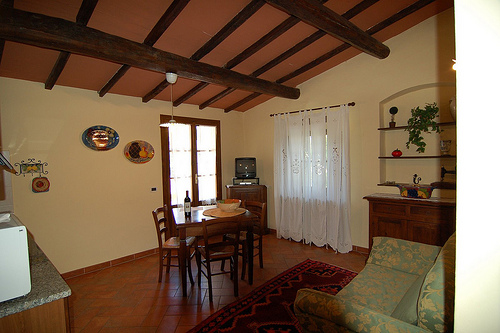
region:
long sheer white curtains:
[258, 98, 377, 275]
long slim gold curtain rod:
[265, 98, 370, 116]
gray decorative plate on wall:
[69, 118, 125, 154]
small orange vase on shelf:
[385, 143, 405, 158]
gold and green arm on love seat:
[299, 290, 387, 314]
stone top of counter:
[31, 259, 81, 296]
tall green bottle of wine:
[178, 188, 199, 222]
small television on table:
[230, 141, 269, 177]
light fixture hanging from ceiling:
[152, 73, 196, 130]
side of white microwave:
[10, 222, 46, 278]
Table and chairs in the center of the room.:
[130, 178, 279, 291]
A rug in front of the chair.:
[198, 246, 362, 318]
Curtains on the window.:
[268, 96, 367, 247]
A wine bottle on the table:
[170, 188, 207, 220]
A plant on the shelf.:
[391, 98, 449, 158]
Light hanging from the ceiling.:
[155, 58, 181, 133]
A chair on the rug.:
[288, 224, 448, 330]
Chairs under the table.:
[175, 203, 275, 288]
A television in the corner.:
[219, 147, 274, 193]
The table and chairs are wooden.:
[159, 188, 276, 286]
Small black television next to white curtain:
[232, 152, 259, 182]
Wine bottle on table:
[181, 189, 194, 216]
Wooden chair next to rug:
[195, 216, 242, 306]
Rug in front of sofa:
[188, 250, 358, 332]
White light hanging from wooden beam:
[155, 71, 187, 131]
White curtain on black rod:
[268, 104, 355, 256]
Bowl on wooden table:
[217, 197, 245, 213]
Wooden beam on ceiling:
[0, 3, 307, 100]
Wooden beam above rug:
[267, 0, 394, 59]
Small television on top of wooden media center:
[232, 154, 257, 179]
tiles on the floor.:
[115, 293, 150, 315]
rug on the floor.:
[298, 268, 328, 280]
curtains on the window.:
[310, 135, 335, 186]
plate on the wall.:
[85, 121, 116, 156]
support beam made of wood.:
[310, 13, 367, 47]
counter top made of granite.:
[37, 265, 48, 297]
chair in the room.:
[363, 261, 408, 301]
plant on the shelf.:
[406, 110, 433, 149]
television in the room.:
[236, 157, 255, 177]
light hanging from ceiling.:
[165, 99, 177, 131]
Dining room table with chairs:
[132, 184, 277, 261]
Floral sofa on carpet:
[302, 236, 379, 313]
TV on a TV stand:
[214, 140, 306, 212]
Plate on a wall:
[83, 116, 126, 165]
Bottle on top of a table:
[171, 183, 193, 222]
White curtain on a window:
[258, 112, 362, 251]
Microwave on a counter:
[1, 201, 53, 295]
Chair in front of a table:
[143, 197, 178, 289]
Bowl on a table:
[222, 195, 242, 219]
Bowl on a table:
[211, 189, 250, 227]